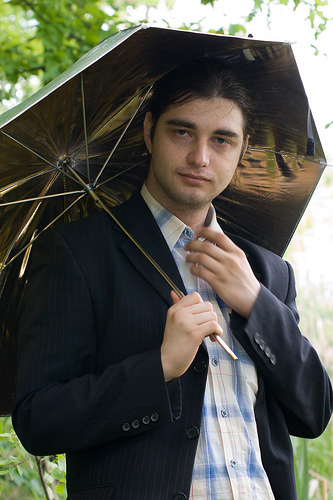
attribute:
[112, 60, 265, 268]
man — standing 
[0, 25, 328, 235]
umbrella — BLACK, SHINY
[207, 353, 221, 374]
buttons — Three 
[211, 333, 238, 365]
handle — pointy  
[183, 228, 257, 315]
hand — up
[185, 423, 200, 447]
button —  black 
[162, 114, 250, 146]
pair —  pair 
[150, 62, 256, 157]
brown hair — brown 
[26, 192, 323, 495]
shirt — BLUE, WHITE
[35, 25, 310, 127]
umbrella —  black , silver 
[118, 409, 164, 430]
buttons — four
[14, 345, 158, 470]
sleeve — each 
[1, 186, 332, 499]
blazer — striped, blue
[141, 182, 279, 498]
shirt — checkered 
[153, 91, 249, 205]
face —  man's